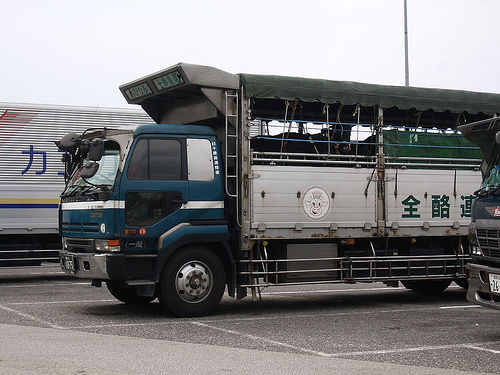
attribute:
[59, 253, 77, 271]
plate — license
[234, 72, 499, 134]
tarp — green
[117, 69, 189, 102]
signs — white, green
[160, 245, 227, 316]
black tire — rubber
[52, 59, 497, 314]
truck — blue, large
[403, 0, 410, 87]
pole — metal, tall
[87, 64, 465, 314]
black truck — large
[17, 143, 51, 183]
writing — blue, foreign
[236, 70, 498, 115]
roof — green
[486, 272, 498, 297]
license plate — white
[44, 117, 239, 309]
front — white, blue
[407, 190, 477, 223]
green writing — foreign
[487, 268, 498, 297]
license — plate, white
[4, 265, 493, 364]
pavement — asphalt, gray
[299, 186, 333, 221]
logo — in a circle, white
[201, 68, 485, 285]
trailer — silver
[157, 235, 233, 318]
wheel — front wheel, black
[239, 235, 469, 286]
steps — metal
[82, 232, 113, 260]
light — head